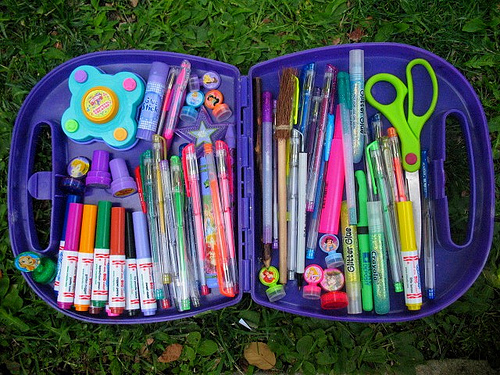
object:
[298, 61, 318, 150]
paintbrush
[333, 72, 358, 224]
pen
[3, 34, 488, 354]
grass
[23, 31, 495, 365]
ground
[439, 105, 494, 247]
handle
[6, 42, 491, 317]
art box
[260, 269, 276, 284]
ariel picture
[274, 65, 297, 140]
bristles